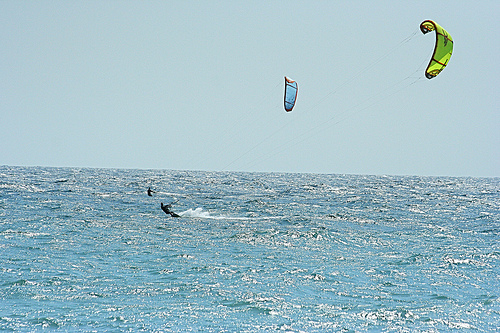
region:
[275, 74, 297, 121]
A blue kite above the water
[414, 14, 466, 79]
A green kite above the water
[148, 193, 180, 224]
A person black in water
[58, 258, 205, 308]
A blue water surface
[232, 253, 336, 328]
A blue water surface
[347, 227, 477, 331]
A blue water surface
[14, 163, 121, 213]
A blue water surface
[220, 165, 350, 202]
A blue water surface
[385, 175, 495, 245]
A blue water surface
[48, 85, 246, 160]
A bluesky horizon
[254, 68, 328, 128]
a object in air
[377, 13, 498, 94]
green object in air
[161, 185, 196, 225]
a man in water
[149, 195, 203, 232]
a man diving in water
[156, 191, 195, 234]
a man holding a wire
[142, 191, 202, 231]
a man skating in water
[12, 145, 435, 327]
a beautiful view of water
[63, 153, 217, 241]
two people in water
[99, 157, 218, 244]
two people skating in water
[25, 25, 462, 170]
a clear view of sky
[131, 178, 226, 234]
two people water skiing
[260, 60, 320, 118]
blue water kite in sky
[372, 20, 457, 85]
green water kite in sky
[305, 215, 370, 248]
blue wavy water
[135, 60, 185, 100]
blue sky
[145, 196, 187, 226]
one person leaning back on water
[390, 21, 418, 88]
strings of kite in sky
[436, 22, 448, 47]
design on green kite in sky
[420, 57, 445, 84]
corner of green kite in sky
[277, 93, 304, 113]
corner of blue kite in sky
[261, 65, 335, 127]
the parasail is blue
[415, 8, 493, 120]
the parasail is green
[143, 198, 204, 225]
the man is holding onto the parasail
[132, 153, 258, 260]
the two men are parasailing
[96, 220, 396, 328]
the ocean is choppy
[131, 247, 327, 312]
the ocean is blue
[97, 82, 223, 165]
the sky is baby blue and clear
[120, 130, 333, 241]
the two men are holding onto something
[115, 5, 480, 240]
the two men are holding onto the parasail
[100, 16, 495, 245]
the two men are participating in a sport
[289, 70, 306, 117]
blue sail in mid air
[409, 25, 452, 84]
green sail in mid air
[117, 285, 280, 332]
large body of water below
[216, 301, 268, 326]
light shining off water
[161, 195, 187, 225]
person parasiling in water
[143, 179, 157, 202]
person parasiling in water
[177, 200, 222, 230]
water spraying up from board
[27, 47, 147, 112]
clear blue sky above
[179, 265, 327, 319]
small waves in water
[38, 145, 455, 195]
horizon in background